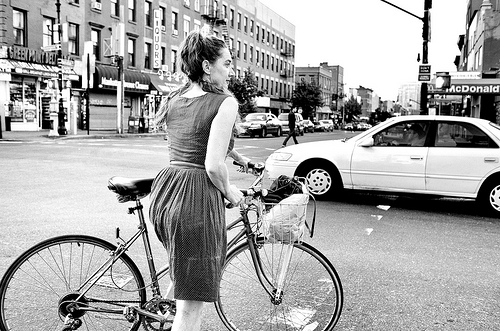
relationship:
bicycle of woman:
[2, 158, 344, 330] [146, 29, 250, 330]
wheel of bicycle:
[0, 233, 148, 331] [2, 158, 344, 330]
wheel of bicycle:
[215, 235, 343, 331] [2, 158, 344, 330]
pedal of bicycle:
[123, 306, 134, 324] [2, 158, 344, 330]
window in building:
[12, 7, 28, 47] [1, 1, 297, 134]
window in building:
[125, 37, 137, 69] [1, 1, 297, 134]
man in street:
[285, 100, 299, 145] [0, 127, 499, 307]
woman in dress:
[146, 29, 250, 330] [146, 88, 236, 302]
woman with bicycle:
[146, 29, 250, 330] [2, 158, 344, 330]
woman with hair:
[146, 29, 250, 330] [180, 29, 226, 93]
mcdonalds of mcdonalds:
[446, 84, 500, 92] [448, 86, 497, 92]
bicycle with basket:
[2, 158, 344, 330] [239, 177, 308, 245]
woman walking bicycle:
[146, 29, 250, 330] [2, 158, 344, 330]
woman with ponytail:
[146, 29, 250, 330] [180, 29, 204, 87]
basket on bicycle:
[239, 177, 308, 245] [2, 158, 344, 330]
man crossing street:
[285, 100, 299, 145] [0, 127, 499, 307]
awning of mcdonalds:
[418, 77, 499, 99] [448, 86, 497, 92]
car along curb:
[235, 111, 285, 139] [74, 134, 170, 141]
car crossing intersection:
[263, 115, 498, 221] [2, 141, 285, 307]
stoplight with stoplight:
[433, 73, 453, 93] [433, 73, 453, 93]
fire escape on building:
[204, 1, 240, 70] [1, 1, 297, 134]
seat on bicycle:
[107, 174, 157, 202] [2, 158, 344, 330]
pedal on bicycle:
[123, 306, 134, 324] [2, 158, 344, 330]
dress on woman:
[146, 88, 236, 302] [146, 29, 250, 330]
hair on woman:
[180, 29, 226, 93] [146, 29, 250, 330]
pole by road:
[54, 2, 70, 138] [1, 136, 166, 169]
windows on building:
[10, 9, 81, 55] [1, 1, 297, 134]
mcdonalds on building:
[446, 84, 500, 92] [456, 1, 499, 120]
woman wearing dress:
[146, 29, 250, 330] [146, 88, 236, 302]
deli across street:
[2, 42, 79, 144] [0, 127, 499, 307]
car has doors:
[263, 115, 498, 221] [352, 145, 499, 197]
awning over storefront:
[96, 63, 152, 94] [86, 88, 146, 133]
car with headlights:
[238, 113, 283, 140] [238, 121, 262, 131]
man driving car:
[403, 123, 427, 149] [263, 115, 498, 221]